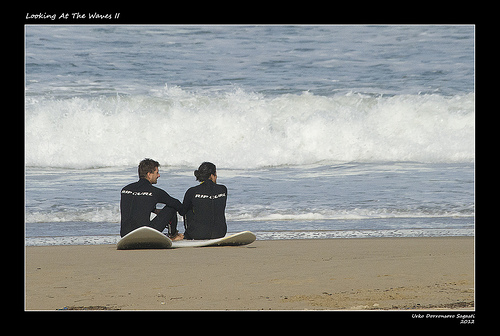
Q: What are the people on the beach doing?
A: Sitting on surfboards.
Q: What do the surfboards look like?
A: White.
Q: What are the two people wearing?
A: Black wet suit.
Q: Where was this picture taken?
A: At the beach.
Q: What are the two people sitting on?
A: Surfboards.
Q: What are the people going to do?
A: Go surfing.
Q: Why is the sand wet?
A: From the waves.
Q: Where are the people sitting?
A: On the beach.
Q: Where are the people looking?
A: At the ocean.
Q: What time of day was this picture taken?
A: During the day time.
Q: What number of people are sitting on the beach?
A: 2.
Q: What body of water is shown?
A: Ocean.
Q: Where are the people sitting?
A: On surfboards.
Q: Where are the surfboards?
A: On sand.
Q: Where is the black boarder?
A: Around photo.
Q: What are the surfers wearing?
A: Wetsuit.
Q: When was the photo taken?
A: 2012.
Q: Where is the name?
A: Bottom right.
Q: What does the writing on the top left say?
A: Looking at the waves.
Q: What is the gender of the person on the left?
A: Male.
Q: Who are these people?
A: Surfers.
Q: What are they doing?
A: Sitting on their boards.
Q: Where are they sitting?
A: On the beach.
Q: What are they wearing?
A: Surfing clothes.